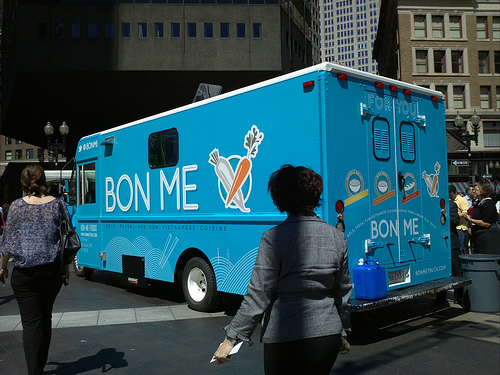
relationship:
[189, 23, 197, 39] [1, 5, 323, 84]
window on building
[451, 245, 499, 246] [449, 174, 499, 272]
line of people